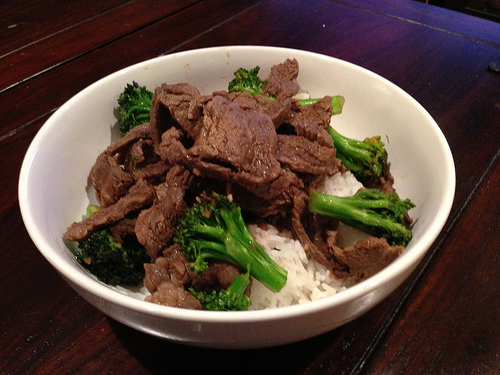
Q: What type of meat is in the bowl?
A: Beef.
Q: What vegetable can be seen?
A: Broccoli.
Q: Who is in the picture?
A: No one.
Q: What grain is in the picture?
A: Rice.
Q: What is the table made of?
A: Wood.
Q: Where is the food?
A: In a bowl.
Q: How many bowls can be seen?
A: 1.